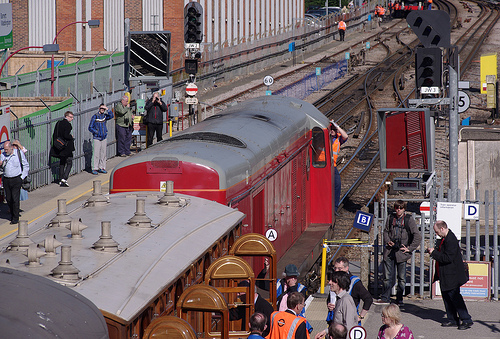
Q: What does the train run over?
A: Tracks.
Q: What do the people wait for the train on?
A: A platform.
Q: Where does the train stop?
A: The station.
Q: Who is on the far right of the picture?
A: A man in a black suit.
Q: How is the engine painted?
A: Red.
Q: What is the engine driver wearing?
A: An orange safety vest.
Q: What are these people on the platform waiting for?
A: The train.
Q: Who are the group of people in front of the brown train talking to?
A: A transit employee.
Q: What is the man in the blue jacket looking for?
A: An approaching train.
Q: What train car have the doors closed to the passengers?
A: The red train car.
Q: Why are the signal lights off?
A: Because the trains are not moving.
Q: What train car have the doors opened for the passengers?
A: The brown train car.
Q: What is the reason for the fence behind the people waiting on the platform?
A: The people waiting will not fell onto the other side of the track.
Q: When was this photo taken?
A: Daytime.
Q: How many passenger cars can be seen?
A: 1.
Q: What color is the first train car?
A: Red.